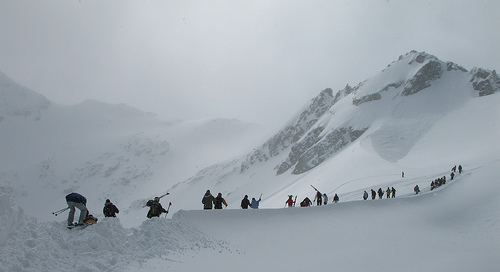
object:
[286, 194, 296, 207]
skiers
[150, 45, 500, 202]
mountain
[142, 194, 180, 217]
poles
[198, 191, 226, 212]
pairs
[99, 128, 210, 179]
snow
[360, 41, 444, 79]
peak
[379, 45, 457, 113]
tip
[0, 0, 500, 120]
sky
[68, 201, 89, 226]
pants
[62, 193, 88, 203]
coats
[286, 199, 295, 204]
coat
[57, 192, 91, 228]
man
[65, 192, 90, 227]
over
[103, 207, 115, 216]
backpacks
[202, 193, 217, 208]
jackets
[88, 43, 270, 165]
clouds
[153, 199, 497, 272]
ground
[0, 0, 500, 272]
daytime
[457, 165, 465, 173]
trails